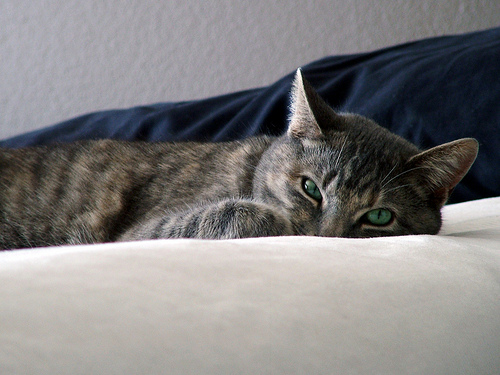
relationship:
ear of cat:
[279, 70, 323, 133] [0, 27, 482, 279]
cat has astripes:
[0, 27, 482, 279] [74, 149, 151, 229]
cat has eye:
[0, 27, 482, 279] [295, 170, 328, 206]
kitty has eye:
[0, 27, 482, 279] [295, 170, 328, 206]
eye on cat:
[295, 170, 328, 206] [0, 65, 480, 253]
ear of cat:
[279, 70, 323, 133] [0, 65, 480, 253]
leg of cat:
[39, 184, 266, 344] [0, 65, 480, 253]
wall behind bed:
[172, 6, 242, 79] [0, 27, 482, 279]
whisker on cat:
[264, 190, 320, 228] [0, 65, 480, 253]